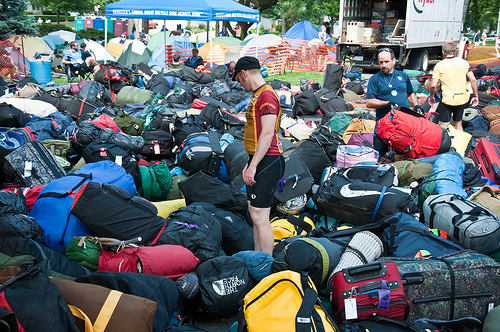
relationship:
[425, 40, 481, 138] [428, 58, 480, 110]
man wearing yellow shirt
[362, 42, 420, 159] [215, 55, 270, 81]
man wearing hat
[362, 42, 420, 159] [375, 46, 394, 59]
man has sunglasses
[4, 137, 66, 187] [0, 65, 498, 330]
duffel bags by duffel bags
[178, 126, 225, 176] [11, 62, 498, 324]
bag on ground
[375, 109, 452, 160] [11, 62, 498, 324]
bag on ground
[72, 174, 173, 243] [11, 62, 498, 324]
luggage on ground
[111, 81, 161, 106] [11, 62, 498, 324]
luggage on ground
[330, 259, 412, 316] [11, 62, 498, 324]
bag on ground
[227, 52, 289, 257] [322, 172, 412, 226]
man on bag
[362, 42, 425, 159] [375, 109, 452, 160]
man on bag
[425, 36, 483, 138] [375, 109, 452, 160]
man on bag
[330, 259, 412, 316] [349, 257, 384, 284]
bag has handle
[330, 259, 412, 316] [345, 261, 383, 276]
bag has handle